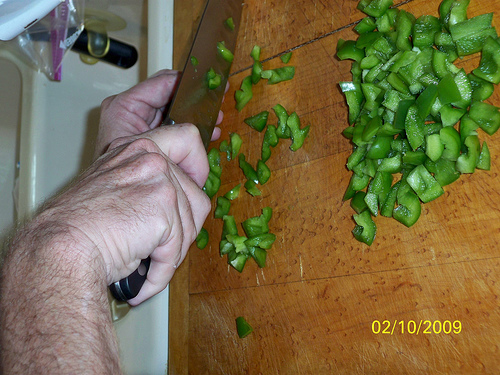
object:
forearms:
[1, 105, 165, 372]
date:
[369, 316, 461, 338]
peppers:
[359, 116, 384, 141]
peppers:
[231, 316, 254, 338]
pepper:
[470, 99, 499, 134]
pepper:
[438, 110, 465, 128]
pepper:
[410, 23, 435, 52]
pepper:
[404, 164, 446, 204]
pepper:
[390, 187, 424, 226]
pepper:
[437, 70, 477, 111]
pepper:
[421, 131, 446, 161]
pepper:
[399, 104, 424, 147]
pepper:
[437, 127, 464, 162]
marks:
[359, 271, 427, 304]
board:
[165, 0, 497, 374]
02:
[370, 317, 391, 334]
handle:
[99, 254, 159, 309]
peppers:
[278, 51, 293, 63]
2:
[423, 318, 432, 335]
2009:
[423, 319, 463, 336]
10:
[398, 319, 418, 336]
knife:
[103, 0, 244, 297]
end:
[111, 255, 155, 300]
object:
[25, 24, 139, 75]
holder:
[51, 4, 131, 75]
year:
[423, 318, 463, 335]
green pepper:
[332, 1, 498, 246]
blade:
[165, 0, 243, 153]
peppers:
[350, 210, 379, 244]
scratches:
[298, 256, 305, 284]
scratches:
[252, 267, 268, 285]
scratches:
[224, 263, 231, 273]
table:
[169, 1, 499, 373]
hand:
[0, 110, 219, 300]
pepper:
[352, 210, 377, 245]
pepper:
[401, 100, 425, 147]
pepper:
[334, 38, 364, 62]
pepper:
[412, 86, 443, 119]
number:
[369, 318, 381, 335]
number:
[380, 317, 391, 333]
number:
[396, 320, 405, 335]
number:
[407, 320, 417, 335]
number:
[422, 319, 432, 334]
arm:
[0, 219, 130, 373]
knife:
[105, 1, 245, 301]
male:
[2, 65, 214, 375]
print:
[367, 316, 463, 336]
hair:
[14, 259, 86, 319]